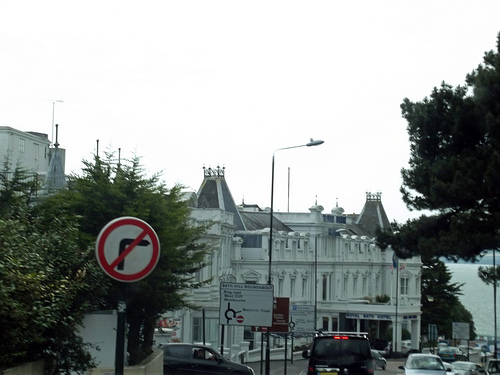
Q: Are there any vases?
A: No, there are no vases.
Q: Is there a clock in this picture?
A: No, there are no clocks.